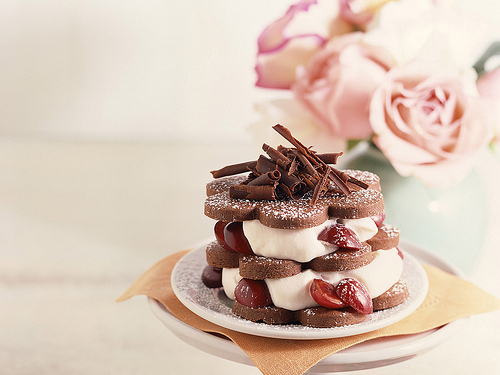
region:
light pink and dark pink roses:
[243, 4, 498, 171]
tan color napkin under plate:
[116, 158, 499, 374]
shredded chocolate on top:
[201, 122, 433, 340]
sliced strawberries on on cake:
[166, 123, 437, 342]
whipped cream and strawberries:
[171, 120, 428, 346]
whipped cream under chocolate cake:
[174, 123, 433, 338]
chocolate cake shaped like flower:
[170, 125, 435, 341]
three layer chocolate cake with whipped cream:
[171, 117, 436, 347]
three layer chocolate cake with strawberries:
[190, 122, 417, 334]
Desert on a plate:
[162, 131, 414, 342]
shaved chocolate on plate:
[222, 123, 332, 197]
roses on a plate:
[250, 5, 498, 152]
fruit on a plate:
[305, 266, 385, 311]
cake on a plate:
[193, 178, 381, 335]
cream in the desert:
[243, 228, 314, 263]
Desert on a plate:
[164, 150, 434, 365]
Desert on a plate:
[191, 130, 364, 322]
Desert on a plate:
[103, 63, 425, 332]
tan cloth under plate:
[118, 252, 498, 374]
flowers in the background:
[244, 0, 498, 182]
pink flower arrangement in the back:
[246, 1, 498, 181]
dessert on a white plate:
[199, 121, 410, 326]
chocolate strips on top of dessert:
[210, 121, 367, 202]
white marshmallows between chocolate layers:
[222, 216, 403, 310]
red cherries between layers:
[215, 221, 376, 312]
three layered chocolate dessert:
[201, 126, 406, 331]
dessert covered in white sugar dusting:
[188, 124, 410, 326]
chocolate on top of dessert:
[208, 123, 368, 203]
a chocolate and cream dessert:
[175, 120, 427, 335]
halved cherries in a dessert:
[305, 270, 380, 310]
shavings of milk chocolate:
[205, 120, 370, 206]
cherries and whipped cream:
[205, 215, 390, 260]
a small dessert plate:
[170, 240, 430, 341]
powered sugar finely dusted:
[175, 151, 425, 332]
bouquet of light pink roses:
[251, 1, 491, 176]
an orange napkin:
[120, 250, 495, 370]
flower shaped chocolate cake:
[200, 160, 385, 225]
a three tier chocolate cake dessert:
[111, 125, 496, 371]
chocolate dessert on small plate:
[171, 123, 426, 337]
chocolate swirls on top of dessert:
[231, 123, 355, 194]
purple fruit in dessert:
[311, 276, 376, 316]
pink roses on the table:
[252, 44, 496, 173]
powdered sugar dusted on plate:
[173, 253, 231, 318]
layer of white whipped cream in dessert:
[243, 220, 378, 257]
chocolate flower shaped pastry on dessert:
[203, 170, 387, 222]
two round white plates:
[144, 241, 464, 373]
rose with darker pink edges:
[252, 40, 293, 93]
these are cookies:
[208, 156, 397, 351]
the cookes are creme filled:
[203, 182, 350, 295]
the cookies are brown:
[216, 188, 320, 241]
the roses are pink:
[281, 42, 434, 128]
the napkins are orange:
[132, 255, 207, 334]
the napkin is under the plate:
[139, 271, 247, 356]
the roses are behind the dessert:
[247, 13, 484, 133]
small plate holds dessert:
[139, 228, 475, 374]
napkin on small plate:
[112, 221, 498, 373]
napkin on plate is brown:
[110, 233, 498, 372]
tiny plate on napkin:
[165, 231, 435, 343]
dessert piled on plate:
[183, 114, 420, 334]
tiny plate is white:
[169, 225, 432, 341]